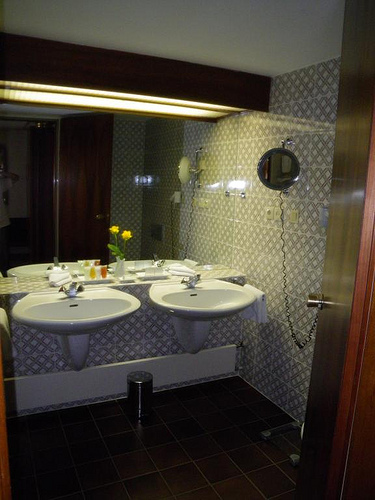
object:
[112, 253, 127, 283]
vase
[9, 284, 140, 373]
sink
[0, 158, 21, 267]
person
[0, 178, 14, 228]
shirt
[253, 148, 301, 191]
mirror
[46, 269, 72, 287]
washrags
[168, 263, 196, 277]
washrags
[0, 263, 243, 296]
ledge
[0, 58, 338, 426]
wall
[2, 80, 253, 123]
light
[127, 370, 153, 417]
trash can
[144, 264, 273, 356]
sink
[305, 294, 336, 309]
door handle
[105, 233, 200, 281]
sink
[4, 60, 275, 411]
wall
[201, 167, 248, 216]
light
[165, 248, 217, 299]
sink faucet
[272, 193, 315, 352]
cord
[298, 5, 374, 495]
door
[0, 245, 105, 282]
sink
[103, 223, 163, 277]
yellow flower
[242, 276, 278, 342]
towel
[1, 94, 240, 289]
mirror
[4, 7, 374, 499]
bathroom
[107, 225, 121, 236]
flower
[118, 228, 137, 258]
flower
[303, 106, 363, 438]
door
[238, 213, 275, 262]
wall